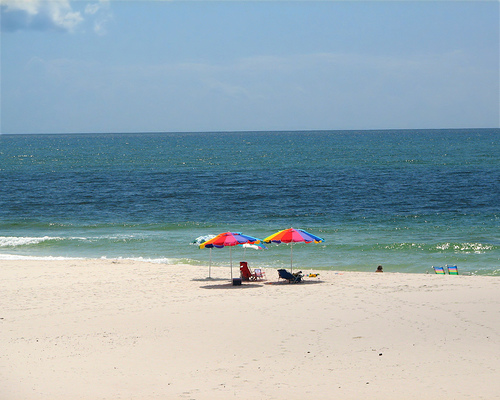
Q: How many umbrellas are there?
A: 2.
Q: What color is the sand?
A: White.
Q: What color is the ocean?
A: Blue.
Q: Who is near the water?
A: A person sitting down.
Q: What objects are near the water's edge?
A: Chairs.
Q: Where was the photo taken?
A: At the beach.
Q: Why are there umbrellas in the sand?
A: To shield the sun.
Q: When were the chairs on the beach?
A: During daylight hours.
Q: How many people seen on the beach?
A: One.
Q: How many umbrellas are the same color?
A: Two.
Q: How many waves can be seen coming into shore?
A: One.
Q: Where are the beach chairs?
A: By the water.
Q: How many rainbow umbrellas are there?
A: Two.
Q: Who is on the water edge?
A: A boy.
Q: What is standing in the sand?
A: Umbrellas.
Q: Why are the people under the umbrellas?
A: For shade.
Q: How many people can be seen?
A: One.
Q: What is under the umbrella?
A: Chaisse lounge chairs.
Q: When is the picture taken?
A: Afternoon.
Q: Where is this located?
A: On the beach.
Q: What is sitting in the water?
A: Two chairs.